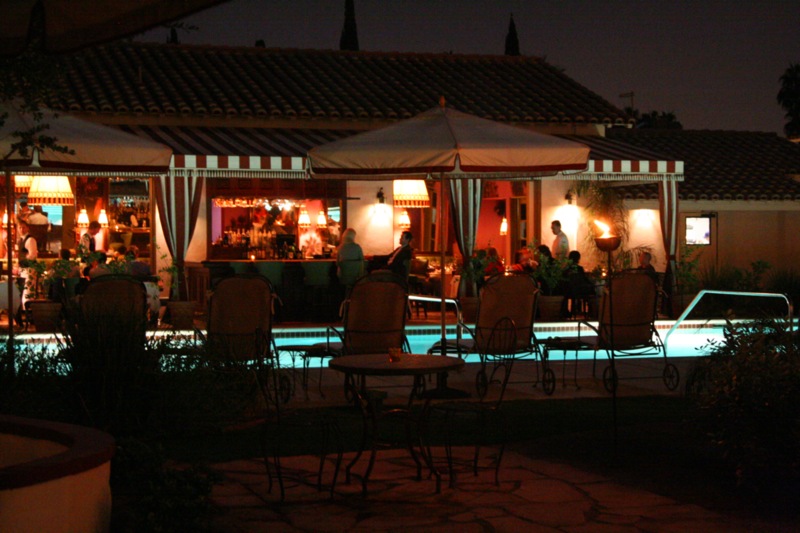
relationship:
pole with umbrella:
[444, 181, 455, 365] [300, 95, 598, 188]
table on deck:
[326, 344, 478, 502] [5, 363, 774, 530]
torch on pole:
[592, 226, 624, 253] [603, 250, 617, 280]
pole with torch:
[603, 254, 627, 432] [592, 232, 629, 252]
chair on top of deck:
[428, 270, 547, 395] [5, 363, 774, 530]